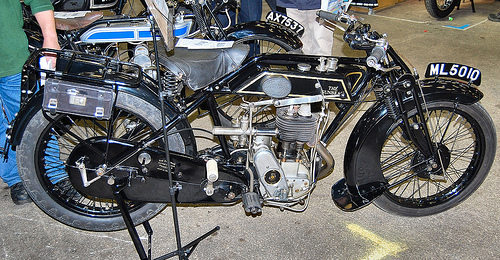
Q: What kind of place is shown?
A: It is a museum.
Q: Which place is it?
A: It is a museum.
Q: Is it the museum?
A: Yes, it is the museum.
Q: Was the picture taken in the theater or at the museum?
A: It was taken at the museum.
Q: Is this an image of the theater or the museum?
A: It is showing the museum.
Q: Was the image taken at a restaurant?
A: No, the picture was taken in a museum.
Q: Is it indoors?
A: Yes, it is indoors.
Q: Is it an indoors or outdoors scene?
A: It is indoors.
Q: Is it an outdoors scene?
A: No, it is indoors.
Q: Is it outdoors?
A: No, it is indoors.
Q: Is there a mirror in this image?
A: No, there are no mirrors.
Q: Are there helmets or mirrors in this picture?
A: No, there are no mirrors or helmets.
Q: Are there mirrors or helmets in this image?
A: No, there are no mirrors or helmets.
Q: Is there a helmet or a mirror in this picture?
A: No, there are no mirrors or helmets.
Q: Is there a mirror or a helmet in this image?
A: No, there are no mirrors or helmets.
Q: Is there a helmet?
A: No, there are no helmets.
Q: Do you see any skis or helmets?
A: No, there are no helmets or skis.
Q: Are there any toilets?
A: No, there are no toilets.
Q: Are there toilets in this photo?
A: No, there are no toilets.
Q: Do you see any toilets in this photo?
A: No, there are no toilets.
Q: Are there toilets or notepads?
A: No, there are no toilets or notepads.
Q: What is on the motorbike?
A: The seat is on the motorbike.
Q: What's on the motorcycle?
A: The seat is on the motorbike.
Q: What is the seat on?
A: The seat is on the motorcycle.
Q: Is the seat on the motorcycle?
A: Yes, the seat is on the motorcycle.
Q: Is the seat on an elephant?
A: No, the seat is on the motorcycle.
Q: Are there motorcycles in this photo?
A: Yes, there is a motorcycle.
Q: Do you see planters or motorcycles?
A: Yes, there is a motorcycle.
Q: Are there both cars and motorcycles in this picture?
A: No, there is a motorcycle but no cars.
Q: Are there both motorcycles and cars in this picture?
A: No, there is a motorcycle but no cars.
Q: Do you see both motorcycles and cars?
A: No, there is a motorcycle but no cars.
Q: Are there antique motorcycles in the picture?
A: Yes, there is an antique motorcycle.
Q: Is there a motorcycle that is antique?
A: Yes, there is a motorcycle that is antique.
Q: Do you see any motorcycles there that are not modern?
A: Yes, there is a antique motorcycle.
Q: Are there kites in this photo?
A: No, there are no kites.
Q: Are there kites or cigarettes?
A: No, there are no kites or cigarettes.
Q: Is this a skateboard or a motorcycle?
A: This is a motorcycle.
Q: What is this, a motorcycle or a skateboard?
A: This is a motorcycle.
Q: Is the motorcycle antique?
A: Yes, the motorcycle is antique.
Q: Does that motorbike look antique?
A: Yes, the motorbike is antique.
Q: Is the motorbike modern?
A: No, the motorbike is antique.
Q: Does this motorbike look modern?
A: No, the motorbike is antique.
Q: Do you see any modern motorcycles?
A: No, there is a motorcycle but it is antique.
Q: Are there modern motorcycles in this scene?
A: No, there is a motorcycle but it is antique.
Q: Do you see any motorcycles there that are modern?
A: No, there is a motorcycle but it is antique.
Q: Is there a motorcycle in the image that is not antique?
A: No, there is a motorcycle but it is antique.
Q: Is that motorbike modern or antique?
A: The motorbike is antique.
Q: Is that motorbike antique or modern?
A: The motorbike is antique.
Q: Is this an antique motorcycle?
A: Yes, this is an antique motorcycle.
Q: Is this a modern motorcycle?
A: No, this is an antique motorcycle.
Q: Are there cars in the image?
A: No, there are no cars.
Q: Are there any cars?
A: No, there are no cars.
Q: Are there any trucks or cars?
A: No, there are no cars or trucks.